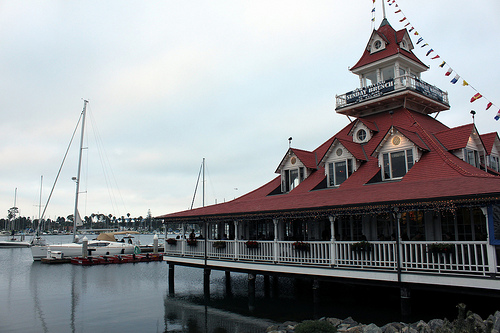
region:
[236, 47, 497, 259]
This is a building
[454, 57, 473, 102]
These are flags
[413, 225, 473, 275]
This is a picture of a plant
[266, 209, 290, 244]
This is a wooden bar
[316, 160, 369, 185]
This is a window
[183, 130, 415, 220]
These are three windows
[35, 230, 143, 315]
This is a harbor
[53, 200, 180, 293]
This is a sailboat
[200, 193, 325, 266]
This is a roof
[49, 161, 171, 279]
This is a white boat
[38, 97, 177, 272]
white sailboat in harbor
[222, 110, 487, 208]
red roof of building on right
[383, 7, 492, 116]
line hanging with flags on it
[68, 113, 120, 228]
mast on boat without sail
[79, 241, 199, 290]
wooden docks in harbor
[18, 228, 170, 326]
calm water under boats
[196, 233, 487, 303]
white rail on side of building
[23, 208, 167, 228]
dark trees off in distance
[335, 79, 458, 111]
small platform on building top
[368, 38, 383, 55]
small round window on top of building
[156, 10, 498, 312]
a building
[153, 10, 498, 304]
a building on the water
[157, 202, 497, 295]
the building has a wrap around white porch with railing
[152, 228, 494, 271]
flowers are hung on the railing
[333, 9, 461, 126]
a railing surrounds the peak of the roof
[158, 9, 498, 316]
the building is a restaurant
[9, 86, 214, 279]
boats are in the water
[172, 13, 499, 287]
the building has a steep red roof with multiple peaks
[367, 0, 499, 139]
flags are hanging from the top of the building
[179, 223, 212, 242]
a person is standing on the porch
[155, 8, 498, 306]
building on stilts on water in a harbor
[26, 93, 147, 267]
sailboat in water docked in a harbor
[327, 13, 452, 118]
top of a red building on the water in a harbor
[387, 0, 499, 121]
flags hanging on a red building on water in harbor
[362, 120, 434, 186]
side window with light on on a building in habor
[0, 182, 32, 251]
small sailboat docked in a harbor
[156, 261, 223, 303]
stilts holding a red building up in a harbor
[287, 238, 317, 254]
flower box on a rail on a building in a harbor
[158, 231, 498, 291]
railing on a red building in a harbor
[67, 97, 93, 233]
top pole of a sailboat docked in a harbor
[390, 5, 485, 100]
Pendants hanging from the building.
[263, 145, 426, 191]
Windows on the building.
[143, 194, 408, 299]
The building is off the water.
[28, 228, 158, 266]
Boat in the water.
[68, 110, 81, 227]
The boat has a sail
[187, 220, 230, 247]
People in the restaurant.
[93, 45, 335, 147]
The sky is clear and blue.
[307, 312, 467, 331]
Rocks on the shoreline.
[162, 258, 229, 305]
Poles in the water.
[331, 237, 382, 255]
Flowers on the gate